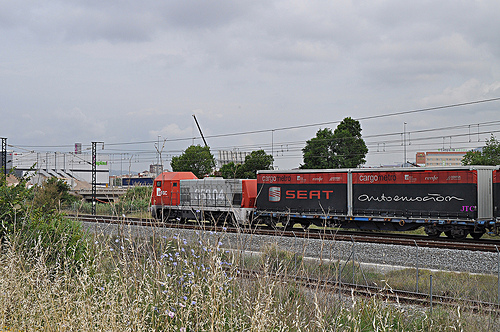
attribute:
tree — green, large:
[462, 132, 496, 164]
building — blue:
[16, 115, 148, 240]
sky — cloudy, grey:
[4, 7, 499, 169]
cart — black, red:
[248, 163, 492, 225]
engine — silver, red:
[143, 167, 262, 221]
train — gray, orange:
[138, 147, 495, 239]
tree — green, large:
[303, 87, 388, 198]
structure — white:
[10, 101, 142, 224]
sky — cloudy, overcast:
[4, 5, 497, 148]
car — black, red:
[347, 155, 497, 233]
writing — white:
[355, 189, 463, 202]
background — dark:
[254, 171, 349, 215]